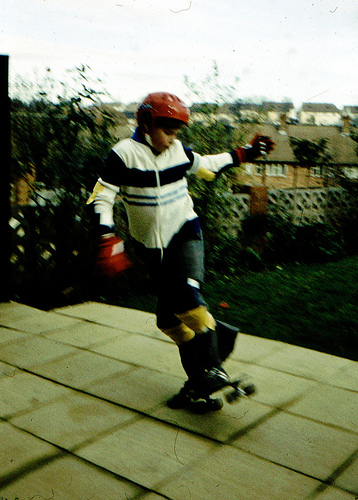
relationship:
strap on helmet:
[141, 134, 152, 145] [136, 92, 188, 124]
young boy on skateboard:
[113, 86, 251, 389] [154, 310, 252, 426]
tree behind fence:
[12, 78, 89, 169] [3, 200, 110, 298]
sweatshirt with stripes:
[82, 134, 235, 260] [115, 180, 188, 212]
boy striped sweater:
[87, 91, 278, 397] [85, 126, 243, 258]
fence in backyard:
[198, 185, 357, 238] [10, 91, 353, 497]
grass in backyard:
[99, 245, 356, 359] [9, 160, 353, 497]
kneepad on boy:
[176, 305, 217, 333] [87, 91, 277, 397]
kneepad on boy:
[162, 321, 195, 341] [87, 91, 277, 397]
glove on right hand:
[93, 233, 131, 276] [74, 125, 130, 273]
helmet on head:
[136, 92, 190, 126] [138, 91, 187, 152]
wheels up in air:
[194, 384, 257, 417] [3, 1, 352, 493]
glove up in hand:
[93, 233, 131, 272] [102, 234, 127, 270]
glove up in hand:
[236, 131, 273, 165] [238, 136, 274, 158]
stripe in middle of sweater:
[104, 156, 196, 186] [86, 136, 244, 248]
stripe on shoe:
[215, 371, 229, 382] [204, 351, 239, 382]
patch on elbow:
[195, 166, 228, 178] [192, 164, 222, 181]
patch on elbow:
[86, 179, 104, 206] [88, 177, 102, 212]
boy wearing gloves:
[87, 91, 278, 397] [230, 129, 278, 164]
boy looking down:
[87, 91, 277, 397] [88, 150, 240, 394]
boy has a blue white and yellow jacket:
[87, 91, 278, 397] [91, 124, 238, 234]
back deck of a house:
[46, 396, 314, 485] [198, 217, 312, 396]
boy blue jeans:
[87, 91, 277, 397] [154, 220, 205, 314]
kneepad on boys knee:
[159, 321, 195, 341] [137, 296, 214, 361]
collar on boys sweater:
[126, 125, 143, 138] [104, 143, 201, 241]